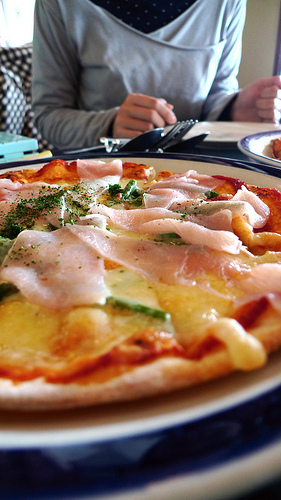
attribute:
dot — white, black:
[130, 5, 138, 9]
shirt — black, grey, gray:
[130, 3, 180, 20]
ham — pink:
[49, 220, 111, 246]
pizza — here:
[12, 162, 244, 394]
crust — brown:
[119, 363, 179, 395]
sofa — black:
[4, 69, 37, 107]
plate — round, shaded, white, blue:
[149, 139, 201, 165]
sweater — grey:
[37, 39, 195, 98]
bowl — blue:
[238, 140, 260, 156]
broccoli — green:
[114, 187, 137, 205]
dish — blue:
[197, 162, 233, 189]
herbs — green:
[114, 300, 156, 327]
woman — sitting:
[30, 14, 242, 135]